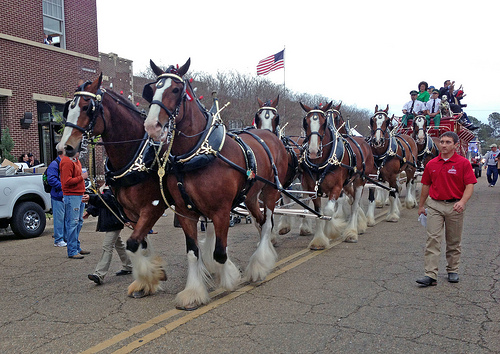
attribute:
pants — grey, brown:
[425, 198, 463, 277]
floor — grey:
[0, 161, 499, 354]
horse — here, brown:
[145, 57, 300, 311]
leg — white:
[174, 251, 215, 310]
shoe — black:
[415, 271, 438, 286]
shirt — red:
[421, 152, 478, 202]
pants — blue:
[63, 196, 83, 256]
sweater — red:
[59, 156, 85, 195]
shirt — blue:
[45, 155, 63, 201]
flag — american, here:
[256, 49, 285, 76]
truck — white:
[0, 175, 52, 238]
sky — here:
[96, 0, 500, 125]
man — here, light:
[418, 130, 478, 283]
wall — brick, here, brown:
[0, 2, 137, 183]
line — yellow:
[77, 200, 423, 353]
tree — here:
[187, 71, 372, 139]